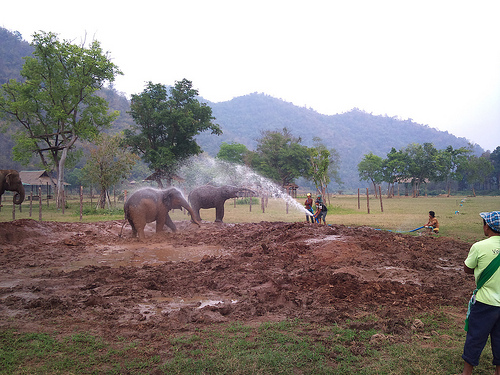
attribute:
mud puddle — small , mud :
[126, 287, 246, 317]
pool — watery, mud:
[91, 236, 244, 269]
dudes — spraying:
[255, 169, 353, 237]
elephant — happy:
[107, 160, 324, 241]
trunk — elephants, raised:
[239, 183, 268, 198]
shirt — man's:
[453, 235, 498, 301]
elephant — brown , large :
[179, 168, 275, 233]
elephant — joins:
[87, 179, 203, 245]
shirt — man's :
[466, 235, 498, 307]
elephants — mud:
[109, 139, 273, 261]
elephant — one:
[119, 186, 199, 235]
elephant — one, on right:
[186, 185, 256, 225]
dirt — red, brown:
[4, 215, 476, 338]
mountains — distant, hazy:
[78, 37, 491, 194]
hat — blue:
[477, 209, 497, 233]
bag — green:
[456, 257, 498, 327]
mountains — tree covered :
[198, 96, 427, 147]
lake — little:
[57, 229, 266, 279]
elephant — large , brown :
[119, 183, 203, 242]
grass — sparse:
[5, 318, 493, 375]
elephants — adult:
[117, 181, 266, 240]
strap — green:
[474, 255, 499, 295]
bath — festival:
[117, 152, 330, 235]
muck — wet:
[9, 219, 480, 340]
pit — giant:
[3, 235, 435, 316]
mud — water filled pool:
[0, 238, 459, 333]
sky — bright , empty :
[137, 1, 479, 71]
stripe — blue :
[473, 263, 483, 296]